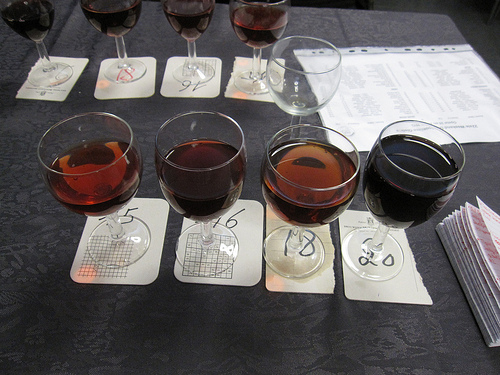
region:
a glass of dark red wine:
[342, 120, 467, 279]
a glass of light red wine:
[32, 114, 153, 270]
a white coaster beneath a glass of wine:
[93, 58, 156, 103]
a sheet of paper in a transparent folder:
[292, 44, 499, 153]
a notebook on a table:
[437, 197, 498, 349]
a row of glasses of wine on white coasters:
[38, 110, 466, 287]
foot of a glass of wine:
[26, 41, 75, 90]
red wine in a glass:
[161, 139, 245, 220]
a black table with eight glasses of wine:
[4, 0, 498, 373]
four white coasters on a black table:
[69, 196, 431, 305]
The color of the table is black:
[76, 304, 467, 369]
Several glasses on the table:
[1, 8, 493, 349]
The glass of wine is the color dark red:
[37, 117, 154, 296]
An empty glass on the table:
[268, 24, 346, 127]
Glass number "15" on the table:
[60, 204, 157, 281]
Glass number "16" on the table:
[164, 168, 259, 291]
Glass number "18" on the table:
[255, 165, 342, 302]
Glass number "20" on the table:
[339, 133, 432, 328]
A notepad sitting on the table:
[433, 195, 498, 352]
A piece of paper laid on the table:
[287, 31, 498, 156]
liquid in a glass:
[274, 128, 356, 230]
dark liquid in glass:
[373, 152, 468, 227]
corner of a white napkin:
[409, 283, 445, 320]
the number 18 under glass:
[265, 230, 330, 272]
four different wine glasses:
[15, 123, 475, 253]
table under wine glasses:
[103, 300, 225, 364]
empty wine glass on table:
[245, 38, 354, 124]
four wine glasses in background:
[3, 7, 294, 95]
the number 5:
[117, 202, 144, 232]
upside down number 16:
[171, 68, 216, 105]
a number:
[209, 219, 243, 233]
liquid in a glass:
[56, 143, 123, 195]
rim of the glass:
[197, 163, 223, 179]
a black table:
[179, 325, 324, 367]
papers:
[447, 223, 497, 265]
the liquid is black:
[395, 141, 439, 170]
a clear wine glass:
[267, 42, 339, 105]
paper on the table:
[357, 66, 461, 111]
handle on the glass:
[103, 44, 139, 62]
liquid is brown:
[290, 146, 336, 183]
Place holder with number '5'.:
[69, 194, 167, 285]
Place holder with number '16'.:
[175, 199, 263, 290]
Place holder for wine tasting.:
[268, 204, 335, 294]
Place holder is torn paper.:
[347, 213, 429, 307]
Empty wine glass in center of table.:
[266, 34, 341, 136]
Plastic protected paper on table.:
[301, 43, 498, 145]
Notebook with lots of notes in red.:
[439, 197, 497, 346]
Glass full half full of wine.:
[32, 110, 152, 268]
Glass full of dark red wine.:
[341, 119, 466, 284]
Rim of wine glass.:
[35, 107, 132, 177]